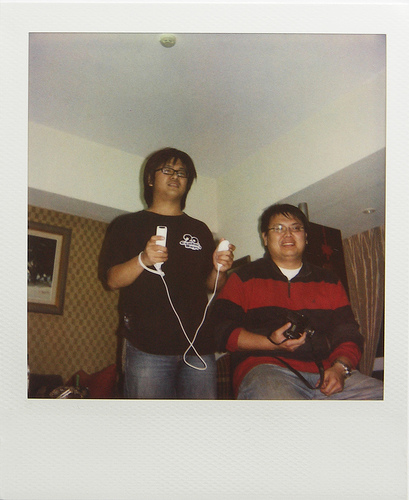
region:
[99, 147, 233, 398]
man holding a video game controller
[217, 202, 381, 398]
man holding a camera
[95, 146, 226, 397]
man wearing a black shirt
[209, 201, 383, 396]
man wearing a red and black shirt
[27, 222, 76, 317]
picture on the wall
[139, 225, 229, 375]
white Wii controller in the man's hands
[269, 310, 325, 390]
black camera in the man's hands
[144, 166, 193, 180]
black eyeglasses on the man's face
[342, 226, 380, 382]
brown curtains over the window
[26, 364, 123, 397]
couch pillows against the wall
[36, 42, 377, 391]
Two Asian boys watching/playing a video game.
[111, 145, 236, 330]
Young boy holding a game controller.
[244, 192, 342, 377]
Young boy holding a camera.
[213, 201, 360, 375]
Young boy wearing a red and black rugby shirt.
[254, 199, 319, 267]
Asian male wearing black-framed glasses.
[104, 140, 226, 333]
Asian boy wearing black-framed glasses and a black t-shirt.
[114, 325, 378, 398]
Blue jeans that are being worn by two young boys.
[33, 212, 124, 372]
Checkered wallpaper on in a living room.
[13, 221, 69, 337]
Framed picture hanging on a living room wall.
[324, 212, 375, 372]
Shiny curtains in a living room.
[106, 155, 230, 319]
a person holding a Wii remote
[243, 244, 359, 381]
a person holding a camera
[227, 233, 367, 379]
a person wearing a black and red shirt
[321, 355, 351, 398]
the left hand of a person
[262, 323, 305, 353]
the right hand of a person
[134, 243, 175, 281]
a Wii remote wrist strap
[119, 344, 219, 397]
a person wearing blue jeans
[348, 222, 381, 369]
curtains on the window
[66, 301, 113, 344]
gold checkered wall paper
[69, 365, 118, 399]
a red pillow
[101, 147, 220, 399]
man wearing blue jeans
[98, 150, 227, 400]
man wearing black shirt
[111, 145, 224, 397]
man wearing eye glasses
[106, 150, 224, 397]
man has dark hair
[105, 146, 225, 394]
man holding game controller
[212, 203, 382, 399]
guy wearing blue pants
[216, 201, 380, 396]
guy wearing striped shirt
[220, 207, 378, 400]
guy wearing eye glasses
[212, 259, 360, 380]
shirt is red and black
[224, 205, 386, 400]
guy wearing wrist watch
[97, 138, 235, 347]
a young man holding game controllers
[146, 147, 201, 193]
a young man wearing glasses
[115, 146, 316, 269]
two young men wearing glasses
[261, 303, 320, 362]
a young man holding a camera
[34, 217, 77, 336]
a picture hanging on a wall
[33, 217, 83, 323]
a picture in a frame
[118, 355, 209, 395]
a young man wearing jeans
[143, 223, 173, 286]
a white game controller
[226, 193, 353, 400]
a young man sitting down